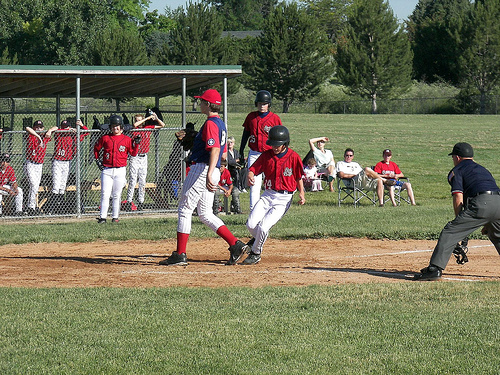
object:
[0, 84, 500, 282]
game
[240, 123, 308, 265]
player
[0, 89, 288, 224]
team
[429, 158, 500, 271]
uniform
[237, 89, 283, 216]
player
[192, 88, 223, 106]
hat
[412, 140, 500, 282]
player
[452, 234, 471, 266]
mitt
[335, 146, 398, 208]
people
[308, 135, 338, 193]
woman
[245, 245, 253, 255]
ball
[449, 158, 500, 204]
shirt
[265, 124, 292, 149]
helmet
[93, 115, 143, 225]
fans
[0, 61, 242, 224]
dugout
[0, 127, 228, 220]
fence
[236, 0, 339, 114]
tree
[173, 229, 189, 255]
sock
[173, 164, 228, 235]
pant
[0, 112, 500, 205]
grass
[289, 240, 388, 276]
dirt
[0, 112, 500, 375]
field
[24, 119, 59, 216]
spectators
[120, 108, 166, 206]
person